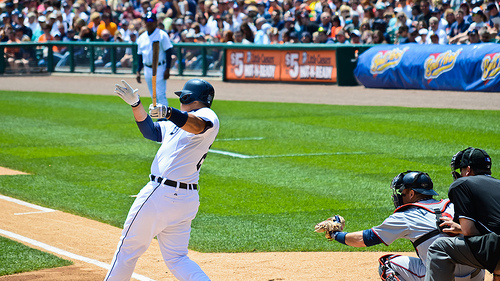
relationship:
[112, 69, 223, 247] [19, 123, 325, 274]
player on field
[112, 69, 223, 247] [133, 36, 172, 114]
player has bat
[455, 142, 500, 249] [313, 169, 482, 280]
umpire behind catcher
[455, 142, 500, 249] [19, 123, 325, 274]
umpire on field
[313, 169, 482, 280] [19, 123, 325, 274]
catcher on field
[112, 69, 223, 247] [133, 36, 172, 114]
player swinging bat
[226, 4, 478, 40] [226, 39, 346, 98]
fans near sign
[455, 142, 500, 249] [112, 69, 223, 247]
umpire near player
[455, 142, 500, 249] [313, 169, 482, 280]
umpire near catcher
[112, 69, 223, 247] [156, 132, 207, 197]
player has shirt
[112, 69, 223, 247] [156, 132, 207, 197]
player wearing shirt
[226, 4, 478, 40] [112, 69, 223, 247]
fans watching player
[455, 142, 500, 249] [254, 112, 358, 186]
umpire in grass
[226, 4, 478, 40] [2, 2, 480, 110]
fans in stands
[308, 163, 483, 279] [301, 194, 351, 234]
catcher in processes of catching ball